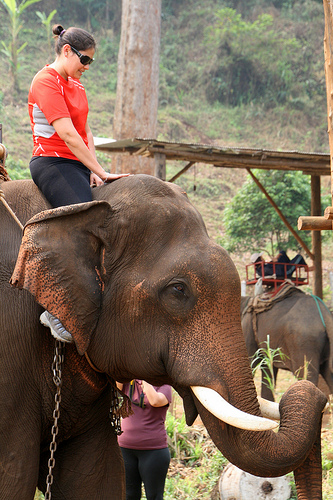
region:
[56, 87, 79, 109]
part of a red top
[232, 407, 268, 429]
part of a tusk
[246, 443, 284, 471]
part of a trunk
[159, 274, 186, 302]
eye of an elephant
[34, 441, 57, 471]
part of a chain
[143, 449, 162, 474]
part of a trouser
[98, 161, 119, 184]
part of a hand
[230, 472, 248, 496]
part of a stone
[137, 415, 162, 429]
part of a top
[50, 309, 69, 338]
part of a shoe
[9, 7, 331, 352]
The picture is taken outside.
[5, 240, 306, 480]
An elephant is in the picture.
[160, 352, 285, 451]
The elephant's tusks are white in color.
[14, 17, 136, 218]
A woman is on top of the elephant.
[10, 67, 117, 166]
The woman's shirt is red in color.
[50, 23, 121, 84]
The woman is wearing sun glasses.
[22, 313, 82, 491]
A chain is wrapped around the elephant's neck.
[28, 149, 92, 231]
The woman is wearing black pants.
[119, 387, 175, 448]
A woman is wearing a purple shirt.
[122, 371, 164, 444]
The woman is wearing a short sleeved shirt.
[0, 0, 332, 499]
elephant exhibit at zoo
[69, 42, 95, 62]
darkly tinted black sunglasses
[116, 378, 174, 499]
woman standing behind animal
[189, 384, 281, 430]
two white elephant tusks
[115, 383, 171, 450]
plain purple woman's t-shirt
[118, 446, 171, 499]
woman's black stretch pants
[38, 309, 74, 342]
gray and blue tennis shoe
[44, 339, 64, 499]
metal chain with large links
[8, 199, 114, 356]
large brown elephant ear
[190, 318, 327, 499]
long elephant trunk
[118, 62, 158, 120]
stem of a tree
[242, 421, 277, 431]
tusk of an elephant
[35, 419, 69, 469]
part of a chain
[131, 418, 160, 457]
part of a top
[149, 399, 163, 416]
part of an elbow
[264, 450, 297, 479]
part of a trunk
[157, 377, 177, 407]
part of a sleeve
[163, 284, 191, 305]
eye of an elephant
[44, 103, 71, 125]
sleeve of a red top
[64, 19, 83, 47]
hair of a lady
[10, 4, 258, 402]
woman riding an elephant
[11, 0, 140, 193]
woman in red shirt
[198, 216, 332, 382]
an elephant with a saddle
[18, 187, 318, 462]
an elephant with tusks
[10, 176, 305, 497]
an elephant wearing a chain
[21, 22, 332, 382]
wooden platform behind an elephant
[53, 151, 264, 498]
person preparing an elephant to be ridden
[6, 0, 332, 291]
hilly terrain behind elephant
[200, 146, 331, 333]
deciduous tree behind elephant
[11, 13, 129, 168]
woman with a hair bun wearing sunglasses